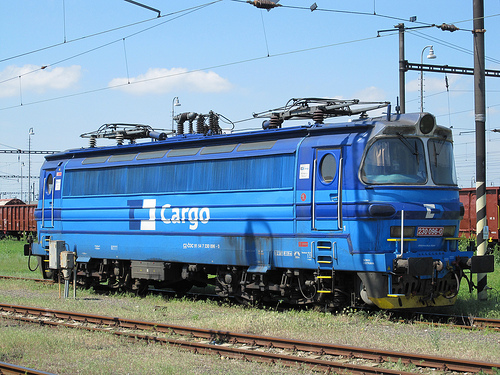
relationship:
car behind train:
[0, 202, 38, 236] [28, 94, 463, 314]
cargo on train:
[158, 191, 215, 233] [28, 94, 463, 314]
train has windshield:
[29, 96, 474, 315] [357, 124, 457, 189]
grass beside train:
[2, 235, 497, 373] [28, 94, 463, 314]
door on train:
[307, 145, 357, 233] [28, 94, 463, 314]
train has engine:
[28, 94, 463, 314] [121, 253, 187, 290]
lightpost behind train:
[417, 35, 441, 104] [7, 105, 449, 278]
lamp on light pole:
[391, 24, 463, 167] [412, 36, 444, 128]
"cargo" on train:
[160, 200, 210, 232] [29, 96, 474, 315]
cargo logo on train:
[124, 204, 213, 233] [28, 94, 463, 314]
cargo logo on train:
[124, 192, 213, 233] [28, 94, 463, 314]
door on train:
[308, 145, 344, 232] [28, 94, 463, 314]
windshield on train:
[348, 121, 459, 203] [28, 94, 463, 314]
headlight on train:
[408, 105, 440, 146] [28, 94, 463, 314]